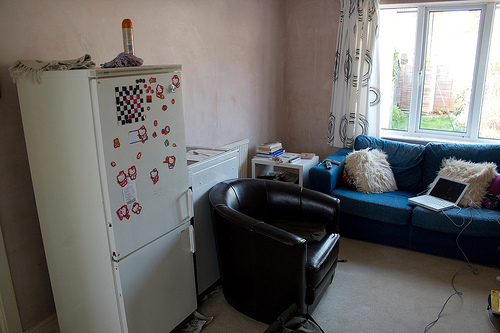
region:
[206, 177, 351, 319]
a black leather chair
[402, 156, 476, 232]
a white laptop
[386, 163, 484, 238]
a laptop on a couch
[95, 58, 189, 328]
a white refrigerator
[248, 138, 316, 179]
a small white table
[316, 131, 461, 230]
a blue couch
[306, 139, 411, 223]
a white pillow on a couch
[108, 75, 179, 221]
several magnets on a refrigerator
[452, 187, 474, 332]
a cord connected to a laptop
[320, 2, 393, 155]
a black and white window curtain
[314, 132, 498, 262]
A blue couch.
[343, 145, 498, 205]
White shaggy small accent pillows.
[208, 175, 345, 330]
A dark leather armchair.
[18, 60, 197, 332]
A refrigerator.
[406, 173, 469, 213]
A white laptop computer.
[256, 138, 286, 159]
A stack of books.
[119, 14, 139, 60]
A can of spray with an orange lid.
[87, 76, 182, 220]
Magnets on the refrigerator.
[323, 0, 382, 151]
White curtains with black round circle designs on it.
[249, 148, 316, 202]
A small white stand.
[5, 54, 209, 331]
a white refrigerator covered in magnets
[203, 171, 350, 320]
a black leather chair with a curved design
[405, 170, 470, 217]
an open white laptop on the couch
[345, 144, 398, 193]
a shaggy white pillow on the couch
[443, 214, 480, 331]
cord to the laptop running across floor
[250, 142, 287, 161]
a small pile of books on a small white table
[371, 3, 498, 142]
a large three paned window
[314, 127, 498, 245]
a blue sagging couch under the window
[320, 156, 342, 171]
two remote controls on the arm of the couch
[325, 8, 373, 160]
a white drape with black circular designs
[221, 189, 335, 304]
this is a sofa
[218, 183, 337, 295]
the sofa is black in color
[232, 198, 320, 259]
the sofa is leather like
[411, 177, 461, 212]
this is a laptop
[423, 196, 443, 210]
the laptop is white in color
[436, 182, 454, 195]
the screen is off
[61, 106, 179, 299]
this is a fridge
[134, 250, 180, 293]
the fridge is white in color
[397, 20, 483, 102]
the window is closed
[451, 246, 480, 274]
this is an electric wire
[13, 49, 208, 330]
The fridge is white.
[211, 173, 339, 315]
The chair is brown.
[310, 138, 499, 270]
THe couch is blue.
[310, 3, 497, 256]
The couch is under the window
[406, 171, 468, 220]
The computer is white.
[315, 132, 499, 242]
The computer is on the couch.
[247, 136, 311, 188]
The table is white.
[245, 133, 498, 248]
The table is next to the couch.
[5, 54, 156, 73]
Rags are on the fridge.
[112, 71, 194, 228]
Magnets are on the fridge.